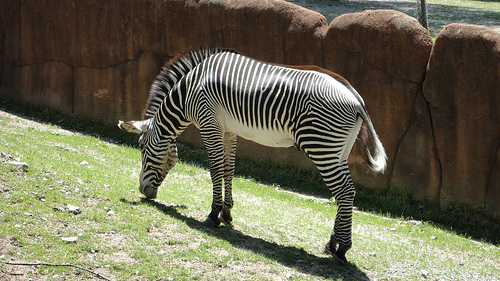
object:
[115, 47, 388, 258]
zebra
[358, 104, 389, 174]
tail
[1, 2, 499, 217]
wall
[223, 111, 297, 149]
belly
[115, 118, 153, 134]
ear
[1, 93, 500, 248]
shadow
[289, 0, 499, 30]
fence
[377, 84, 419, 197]
crack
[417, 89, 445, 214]
crack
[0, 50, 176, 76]
crack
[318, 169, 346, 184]
stripes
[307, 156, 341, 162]
back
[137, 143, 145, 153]
eye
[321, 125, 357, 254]
back leg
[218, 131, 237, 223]
front legs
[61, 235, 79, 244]
rock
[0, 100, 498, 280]
ground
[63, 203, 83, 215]
rock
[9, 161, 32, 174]
rock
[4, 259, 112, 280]
stick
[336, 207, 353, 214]
stripes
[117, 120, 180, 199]
head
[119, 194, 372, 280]
shadow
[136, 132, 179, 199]
downward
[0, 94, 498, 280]
grass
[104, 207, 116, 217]
stone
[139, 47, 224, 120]
mane